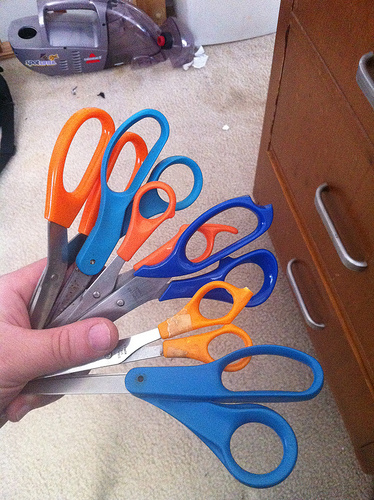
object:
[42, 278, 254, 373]
scissors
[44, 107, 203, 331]
scissors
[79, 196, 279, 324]
scissors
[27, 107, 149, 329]
scissors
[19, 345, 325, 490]
scissors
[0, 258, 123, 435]
hand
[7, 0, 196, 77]
carpet shampooer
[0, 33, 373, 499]
floor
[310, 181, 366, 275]
handle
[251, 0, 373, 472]
dresser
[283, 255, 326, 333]
handle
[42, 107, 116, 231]
handle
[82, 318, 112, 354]
thumbnail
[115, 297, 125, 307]
bolt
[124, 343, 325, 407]
handle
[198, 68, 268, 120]
stain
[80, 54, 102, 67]
logo